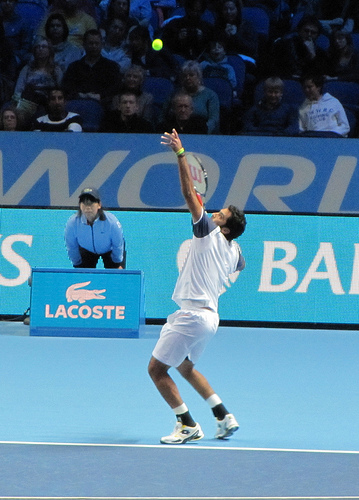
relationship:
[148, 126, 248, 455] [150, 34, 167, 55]
man serving ball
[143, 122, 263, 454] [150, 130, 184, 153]
man has hand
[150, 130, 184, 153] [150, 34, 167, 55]
hand released ball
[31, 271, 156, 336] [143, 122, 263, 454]
sign behind man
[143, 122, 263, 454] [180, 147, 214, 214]
man holding racket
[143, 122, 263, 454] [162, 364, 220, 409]
man has calves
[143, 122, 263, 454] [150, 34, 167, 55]
man hitting ball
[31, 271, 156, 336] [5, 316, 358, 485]
sign on court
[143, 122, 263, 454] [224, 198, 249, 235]
man wearing cap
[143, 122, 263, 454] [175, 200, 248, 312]
man wearing shirt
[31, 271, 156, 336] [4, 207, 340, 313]
sign on stand